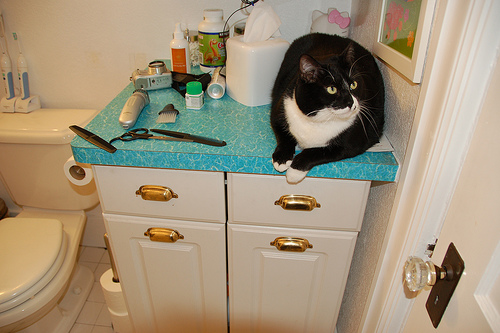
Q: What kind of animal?
A: Cat.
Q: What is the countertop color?
A: Blue.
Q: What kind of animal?
A: Cat.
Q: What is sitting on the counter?
A: A cat.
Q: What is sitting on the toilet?
A: Toothbrushes.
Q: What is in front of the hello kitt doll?
A: A cat.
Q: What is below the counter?
A: Drawers.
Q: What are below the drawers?
A: Cabinets.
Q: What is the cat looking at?
A: The door.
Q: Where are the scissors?
A: On the countertop.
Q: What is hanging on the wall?
A: A picture.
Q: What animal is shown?
A: Cat.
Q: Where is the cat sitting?
A: In the counter.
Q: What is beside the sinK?
A: Toilet.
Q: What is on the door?
A: Doorknob.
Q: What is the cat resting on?
A: Counter top.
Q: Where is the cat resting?
A: Bathroom.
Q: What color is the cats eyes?
A: Yellow.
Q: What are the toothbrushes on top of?
A: The toilet.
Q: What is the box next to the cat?
A: Tissues.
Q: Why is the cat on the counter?
A: Resting.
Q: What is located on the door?
A: Door knob.